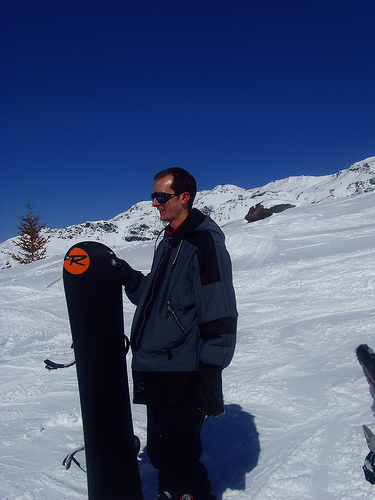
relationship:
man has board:
[117, 167, 239, 496] [61, 242, 146, 499]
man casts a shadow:
[117, 167, 239, 496] [206, 402, 262, 499]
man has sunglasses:
[117, 167, 239, 496] [150, 189, 171, 205]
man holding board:
[117, 167, 239, 496] [61, 242, 146, 499]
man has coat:
[117, 167, 239, 496] [133, 214, 239, 372]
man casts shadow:
[117, 167, 239, 496] [206, 402, 262, 499]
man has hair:
[117, 167, 239, 496] [156, 166, 195, 194]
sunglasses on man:
[150, 189, 171, 205] [117, 167, 239, 496]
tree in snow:
[15, 189, 53, 270] [285, 302, 341, 365]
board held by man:
[61, 242, 146, 499] [117, 167, 239, 496]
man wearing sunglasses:
[117, 167, 239, 496] [150, 189, 171, 205]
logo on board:
[66, 245, 89, 276] [61, 242, 146, 499]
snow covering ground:
[285, 302, 341, 365] [267, 219, 346, 432]